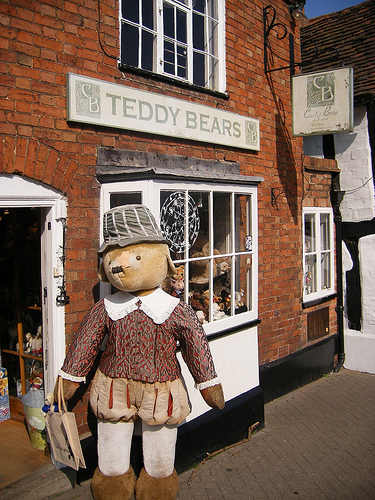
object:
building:
[0, 0, 347, 491]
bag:
[44, 373, 86, 471]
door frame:
[0, 138, 94, 477]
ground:
[313, 82, 333, 105]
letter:
[104, 93, 120, 115]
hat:
[95, 197, 182, 252]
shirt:
[57, 285, 220, 390]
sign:
[64, 70, 259, 150]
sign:
[261, 4, 352, 136]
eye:
[132, 249, 145, 265]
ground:
[223, 454, 282, 496]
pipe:
[326, 173, 348, 375]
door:
[2, 171, 80, 464]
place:
[1, 1, 336, 498]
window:
[119, 0, 227, 95]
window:
[299, 208, 338, 300]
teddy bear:
[63, 193, 236, 498]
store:
[1, 0, 345, 494]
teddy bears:
[161, 238, 248, 331]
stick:
[187, 420, 260, 486]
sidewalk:
[77, 367, 373, 496]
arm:
[180, 318, 220, 388]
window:
[160, 187, 253, 323]